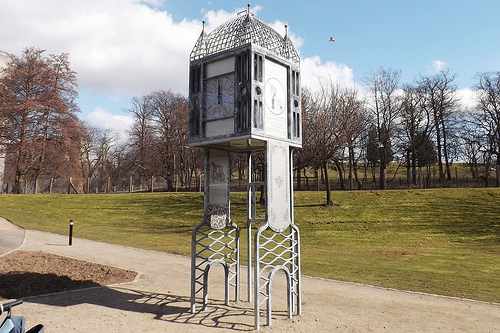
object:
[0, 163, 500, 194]
fence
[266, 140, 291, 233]
silver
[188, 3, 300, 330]
stand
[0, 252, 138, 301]
dirt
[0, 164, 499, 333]
ground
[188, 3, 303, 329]
clock tower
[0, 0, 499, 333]
park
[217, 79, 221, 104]
hand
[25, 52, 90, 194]
tree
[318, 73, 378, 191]
tree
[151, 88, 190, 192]
tree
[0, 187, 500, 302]
lawn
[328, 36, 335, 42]
bird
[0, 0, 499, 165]
blue sky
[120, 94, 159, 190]
tree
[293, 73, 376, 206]
tree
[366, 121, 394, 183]
tree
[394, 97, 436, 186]
tree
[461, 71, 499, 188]
tree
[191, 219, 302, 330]
metal base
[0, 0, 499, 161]
clouds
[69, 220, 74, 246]
black pole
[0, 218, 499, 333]
path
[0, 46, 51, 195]
tree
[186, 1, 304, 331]
metal structure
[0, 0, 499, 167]
sky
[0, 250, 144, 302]
flower bed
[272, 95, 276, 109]
hands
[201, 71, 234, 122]
clock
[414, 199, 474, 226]
grass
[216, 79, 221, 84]
12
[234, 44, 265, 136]
handle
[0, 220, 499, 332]
concrete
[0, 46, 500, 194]
trees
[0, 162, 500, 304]
field